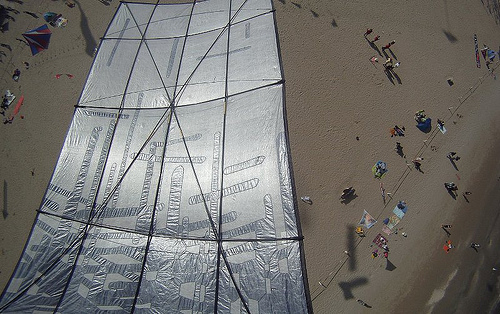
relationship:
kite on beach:
[81, 1, 254, 204] [330, 75, 342, 127]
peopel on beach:
[370, 29, 410, 81] [330, 75, 342, 127]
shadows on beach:
[379, 71, 422, 91] [330, 75, 342, 127]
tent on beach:
[22, 23, 51, 48] [330, 75, 342, 127]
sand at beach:
[384, 5, 426, 17] [330, 75, 342, 127]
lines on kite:
[154, 71, 177, 131] [81, 1, 254, 204]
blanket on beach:
[10, 91, 20, 122] [330, 75, 342, 127]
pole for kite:
[235, 255, 266, 298] [81, 1, 254, 204]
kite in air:
[81, 1, 254, 204] [275, 17, 279, 39]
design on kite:
[114, 51, 162, 80] [81, 1, 254, 204]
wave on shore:
[415, 278, 470, 306] [400, 246, 421, 263]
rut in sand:
[330, 12, 348, 31] [384, 5, 426, 17]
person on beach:
[478, 40, 490, 65] [330, 75, 342, 127]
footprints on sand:
[290, 37, 334, 58] [384, 5, 426, 17]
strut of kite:
[121, 3, 158, 30] [81, 1, 254, 204]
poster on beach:
[206, 59, 257, 96] [330, 75, 342, 127]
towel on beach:
[346, 214, 368, 229] [330, 75, 342, 127]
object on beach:
[15, 95, 26, 101] [330, 75, 342, 127]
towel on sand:
[346, 214, 368, 229] [384, 5, 426, 17]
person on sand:
[478, 40, 490, 65] [384, 5, 426, 17]